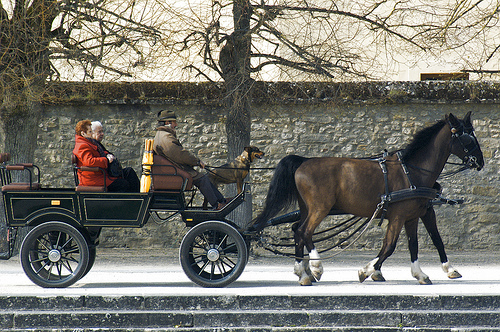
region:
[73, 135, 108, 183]
Woman in a red coat sitting down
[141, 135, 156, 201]
Yellow umbrellas standing up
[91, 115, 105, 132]
White hair on a man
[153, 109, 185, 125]
Man wearing a brown hat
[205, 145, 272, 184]
Standing dog looking right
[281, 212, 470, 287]
Eight horse hooves walking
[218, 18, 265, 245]
Tree behind a horse buggy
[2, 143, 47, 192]
Back seat of a horse buggy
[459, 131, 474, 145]
Blinder over a horse's eye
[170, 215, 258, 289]
Front wheels of a buggy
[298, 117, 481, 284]
this is a horse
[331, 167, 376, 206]
the horse is brown in color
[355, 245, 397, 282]
the legs are behind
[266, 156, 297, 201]
the tail is fury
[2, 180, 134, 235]
this is a chariot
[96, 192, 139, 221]
the chariot is black in color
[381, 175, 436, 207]
it is tied by belts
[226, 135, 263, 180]
this is a dog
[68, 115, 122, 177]
the old men are sitted behind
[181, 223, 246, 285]
the wheel is black in color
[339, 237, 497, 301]
the horseshoe is white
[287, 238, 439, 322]
the horseshoe is white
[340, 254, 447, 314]
the horseshoe is white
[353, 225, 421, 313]
the horseshoe is white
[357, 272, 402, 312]
the horseshoe is white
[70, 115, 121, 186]
a woman in a red coat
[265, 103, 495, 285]
two horses with white feet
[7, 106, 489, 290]
a horse drawn carriage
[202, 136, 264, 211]
the dog in the front seat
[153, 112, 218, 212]
the man driving the carriage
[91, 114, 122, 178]
the passenger with the gray hair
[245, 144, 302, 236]
the long black tail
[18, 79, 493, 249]
the tall stone wall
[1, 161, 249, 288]
a black antique carriage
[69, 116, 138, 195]
an older couple going for a ride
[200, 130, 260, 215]
a dog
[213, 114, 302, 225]
a dog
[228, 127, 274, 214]
a dog